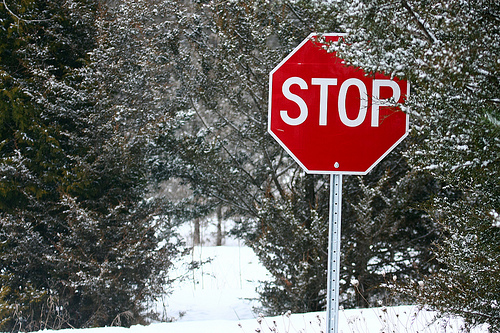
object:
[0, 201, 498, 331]
ground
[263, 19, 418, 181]
bus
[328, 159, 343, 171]
bolt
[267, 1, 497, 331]
tree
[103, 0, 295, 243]
tree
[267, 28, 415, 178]
sign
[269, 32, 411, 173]
street sign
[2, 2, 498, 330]
snow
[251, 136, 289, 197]
branches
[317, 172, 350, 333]
metal pole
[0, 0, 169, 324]
trees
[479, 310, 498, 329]
leaves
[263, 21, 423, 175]
stop sign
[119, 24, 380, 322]
tree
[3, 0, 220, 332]
tree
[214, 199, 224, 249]
trunk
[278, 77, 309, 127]
letter s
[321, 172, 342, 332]
post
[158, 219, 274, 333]
pathway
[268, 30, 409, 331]
sign